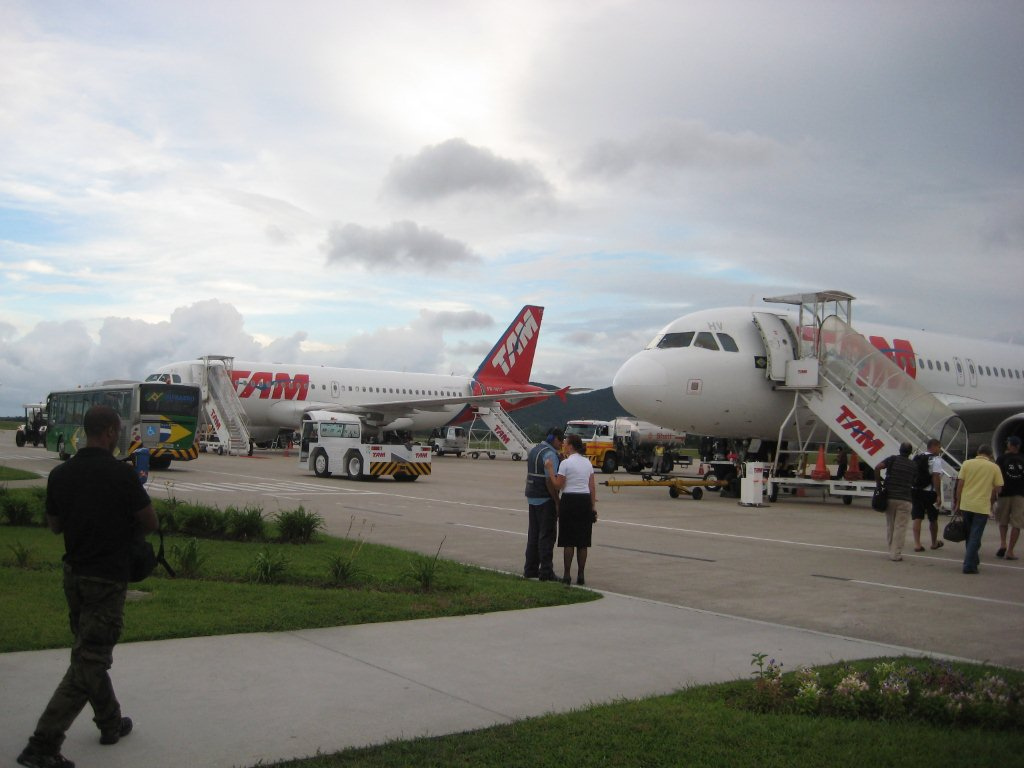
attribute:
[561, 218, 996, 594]
plane — large, white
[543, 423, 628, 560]
shirt — white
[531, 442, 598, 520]
shirt — white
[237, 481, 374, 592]
bush — small, green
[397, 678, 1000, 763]
grass — green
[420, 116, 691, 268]
cloud — large, white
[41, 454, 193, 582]
shirt — short sleeve, black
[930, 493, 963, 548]
bag — small, black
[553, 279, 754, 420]
nose — white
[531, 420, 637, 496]
shirt — white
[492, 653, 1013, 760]
grass — green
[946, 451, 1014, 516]
shirt — yellow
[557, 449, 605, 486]
shirt — white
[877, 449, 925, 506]
shirt — brown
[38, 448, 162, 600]
shirt — black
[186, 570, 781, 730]
sidewalk — concrete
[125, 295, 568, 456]
airplane — red, white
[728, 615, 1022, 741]
flowers — small patch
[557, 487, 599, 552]
skirt — black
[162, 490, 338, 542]
bushes — small, green